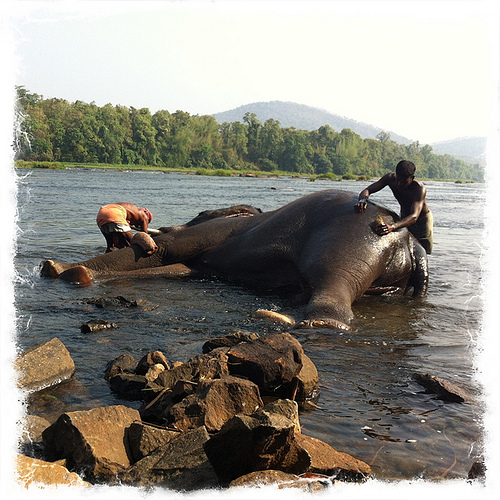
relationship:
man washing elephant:
[353, 160, 433, 255] [35, 177, 442, 345]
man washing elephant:
[96, 202, 153, 254] [35, 177, 442, 345]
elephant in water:
[35, 177, 442, 345] [24, 177, 471, 317]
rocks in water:
[22, 289, 472, 455] [24, 177, 471, 317]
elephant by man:
[35, 177, 442, 345] [353, 160, 433, 255]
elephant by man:
[35, 177, 442, 345] [96, 202, 153, 254]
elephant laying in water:
[35, 177, 442, 345] [24, 177, 471, 317]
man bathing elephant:
[353, 160, 433, 255] [35, 177, 442, 345]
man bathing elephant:
[96, 202, 153, 254] [35, 177, 442, 345]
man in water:
[353, 160, 433, 255] [24, 177, 471, 317]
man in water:
[96, 202, 153, 254] [24, 177, 471, 317]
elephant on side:
[35, 177, 442, 345] [144, 190, 428, 300]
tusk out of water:
[140, 224, 171, 238] [24, 177, 471, 317]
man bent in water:
[92, 202, 156, 260] [24, 177, 471, 317]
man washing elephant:
[92, 202, 156, 260] [35, 177, 442, 345]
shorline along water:
[18, 135, 495, 168] [24, 177, 471, 317]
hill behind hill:
[427, 130, 490, 162] [209, 100, 421, 148]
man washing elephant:
[353, 156, 437, 257] [35, 177, 442, 345]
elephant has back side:
[35, 177, 442, 345] [354, 226, 426, 308]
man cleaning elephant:
[92, 202, 156, 260] [35, 177, 442, 345]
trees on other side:
[16, 84, 485, 182] [21, 0, 498, 178]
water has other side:
[24, 177, 471, 317] [21, 0, 498, 178]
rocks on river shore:
[22, 289, 472, 455] [22, 444, 500, 493]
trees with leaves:
[16, 84, 485, 182] [22, 85, 482, 177]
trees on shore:
[16, 84, 485, 182] [19, 153, 485, 183]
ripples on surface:
[19, 279, 256, 333] [29, 180, 478, 394]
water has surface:
[24, 177, 471, 317] [29, 180, 478, 394]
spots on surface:
[111, 297, 410, 408] [29, 180, 478, 394]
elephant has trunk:
[35, 177, 442, 345] [157, 223, 186, 231]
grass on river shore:
[24, 149, 485, 172] [22, 444, 500, 493]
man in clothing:
[96, 202, 153, 254] [95, 199, 135, 237]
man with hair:
[92, 202, 156, 260] [398, 158, 419, 178]